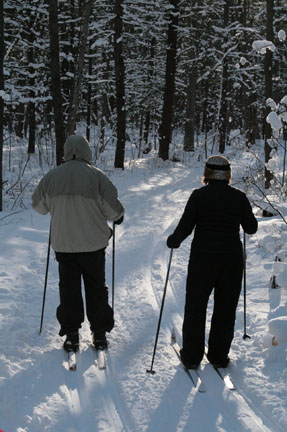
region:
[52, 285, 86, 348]
leg of a person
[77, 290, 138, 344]
leg of a person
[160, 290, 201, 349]
leg of a person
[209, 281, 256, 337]
leg of a person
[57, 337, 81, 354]
feet of a person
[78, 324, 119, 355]
feet of a person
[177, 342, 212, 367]
feet of a person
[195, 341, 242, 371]
feet of a person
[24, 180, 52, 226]
arm of a person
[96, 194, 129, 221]
arm of a person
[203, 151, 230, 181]
Her hat is white.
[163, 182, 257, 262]
Her jacket is black.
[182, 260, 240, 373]
Her pants are black.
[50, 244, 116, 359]
His pants are black.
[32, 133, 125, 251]
His jacket is grey.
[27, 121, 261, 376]
These people are skiing.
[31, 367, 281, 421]
They are leaving tracks in the snow.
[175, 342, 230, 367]
Her boots are black.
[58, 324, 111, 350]
His boots are black.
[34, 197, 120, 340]
They are holding poles.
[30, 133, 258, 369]
two skiers standing in the snow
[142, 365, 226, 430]
shadow cast in the snow by skier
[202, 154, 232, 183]
white and black knit ski cap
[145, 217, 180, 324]
tracks in the snow from skis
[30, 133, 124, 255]
light and dark grey ski jacket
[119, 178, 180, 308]
sun shining on snow through the trees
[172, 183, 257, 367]
black snow suit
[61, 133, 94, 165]
grey hood on ski jacket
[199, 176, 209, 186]
brown hair sticking out from under hat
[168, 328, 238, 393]
long think white skis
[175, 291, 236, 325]
Person wearing black pants.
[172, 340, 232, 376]
2 skis on person's feet.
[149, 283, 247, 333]
Person holding 2 ski poles.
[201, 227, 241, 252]
Person wearing black shirt.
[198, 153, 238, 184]
Person wearing gray hat.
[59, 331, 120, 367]
2 skis on person's feet.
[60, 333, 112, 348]
Person wearing dark boots.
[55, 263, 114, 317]
Person wearing black pants.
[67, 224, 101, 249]
Person wearing gray coat.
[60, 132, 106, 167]
Person has hood over head.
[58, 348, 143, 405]
ground covered in snow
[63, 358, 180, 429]
ground covered in white snow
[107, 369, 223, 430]
snow covering the ground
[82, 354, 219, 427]
white snow covering the ground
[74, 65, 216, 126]
trees covered in snow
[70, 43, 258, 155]
trees covereed in white snow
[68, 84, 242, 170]
snow covering the trees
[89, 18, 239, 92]
white snow covering the trees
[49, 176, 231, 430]
people that are skiing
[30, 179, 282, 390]
people skiing on the snow